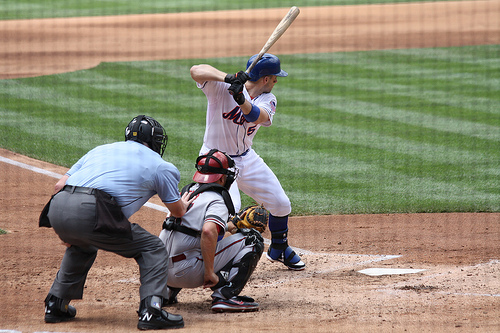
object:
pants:
[197, 145, 291, 218]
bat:
[228, 5, 300, 95]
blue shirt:
[65, 139, 182, 221]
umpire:
[38, 114, 196, 330]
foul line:
[1, 157, 313, 254]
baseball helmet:
[194, 151, 229, 184]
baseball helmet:
[246, 53, 289, 81]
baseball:
[210, 296, 259, 313]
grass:
[317, 60, 499, 194]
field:
[0, 1, 499, 333]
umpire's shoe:
[137, 295, 183, 331]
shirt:
[196, 81, 277, 155]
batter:
[190, 52, 305, 271]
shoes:
[266, 213, 306, 270]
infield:
[0, 0, 499, 213]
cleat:
[228, 202, 268, 233]